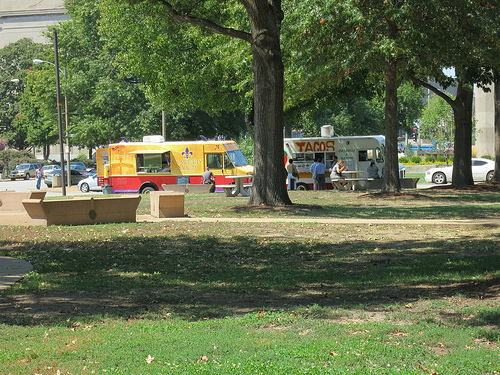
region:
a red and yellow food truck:
[88, 137, 252, 195]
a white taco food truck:
[284, 133, 384, 192]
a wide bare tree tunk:
[246, 6, 289, 208]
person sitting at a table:
[329, 158, 375, 191]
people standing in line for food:
[285, 157, 328, 190]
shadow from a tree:
[2, 233, 497, 331]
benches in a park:
[0, 190, 189, 225]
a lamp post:
[30, 56, 72, 188]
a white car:
[422, 156, 495, 184]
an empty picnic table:
[215, 172, 256, 196]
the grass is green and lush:
[79, 151, 353, 348]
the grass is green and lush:
[141, 223, 248, 372]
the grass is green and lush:
[196, 206, 308, 357]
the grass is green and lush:
[194, 193, 399, 353]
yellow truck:
[83, 122, 247, 192]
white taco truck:
[280, 122, 369, 196]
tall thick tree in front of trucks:
[235, 4, 302, 209]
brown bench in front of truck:
[146, 185, 188, 230]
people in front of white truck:
[282, 134, 390, 210]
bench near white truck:
[324, 161, 376, 203]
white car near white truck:
[428, 145, 497, 188]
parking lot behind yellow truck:
[6, 154, 119, 187]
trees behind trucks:
[16, 29, 387, 134]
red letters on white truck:
[288, 126, 375, 196]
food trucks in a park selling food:
[36, 84, 441, 231]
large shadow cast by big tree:
[59, 217, 408, 338]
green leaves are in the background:
[18, 7, 402, 114]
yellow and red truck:
[98, 139, 254, 190]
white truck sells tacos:
[282, 127, 397, 186]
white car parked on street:
[423, 142, 498, 215]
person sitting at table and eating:
[328, 157, 352, 194]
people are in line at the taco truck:
[281, 157, 328, 193]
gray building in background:
[0, 4, 80, 56]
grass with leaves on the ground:
[29, 307, 241, 365]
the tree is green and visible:
[120, 42, 312, 242]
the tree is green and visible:
[206, 102, 346, 308]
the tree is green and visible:
[144, 3, 340, 323]